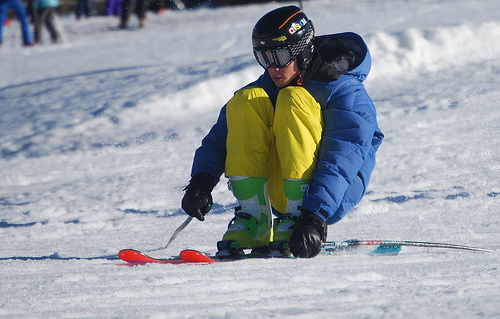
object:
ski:
[118, 249, 182, 266]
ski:
[180, 249, 223, 262]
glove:
[289, 209, 327, 258]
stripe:
[279, 10, 303, 29]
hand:
[181, 185, 213, 221]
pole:
[163, 216, 194, 249]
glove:
[181, 174, 214, 221]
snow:
[13, 66, 161, 154]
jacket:
[189, 31, 384, 224]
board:
[181, 240, 400, 263]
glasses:
[252, 26, 315, 69]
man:
[180, 5, 383, 260]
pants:
[33, 7, 63, 45]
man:
[32, 0, 64, 45]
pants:
[222, 86, 323, 214]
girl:
[180, 5, 382, 260]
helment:
[250, 6, 321, 74]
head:
[252, 6, 315, 88]